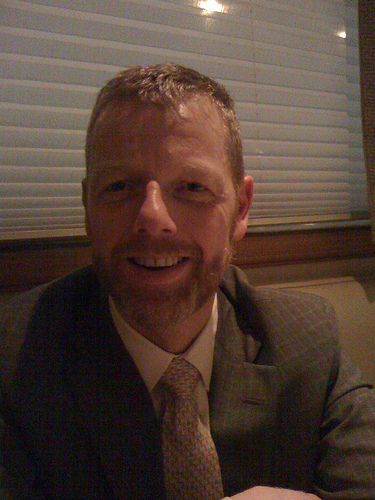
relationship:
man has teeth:
[1, 60, 374, 498] [128, 253, 185, 269]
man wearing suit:
[1, 60, 374, 498] [0, 261, 372, 500]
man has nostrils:
[1, 60, 374, 498] [133, 223, 173, 237]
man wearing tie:
[1, 60, 374, 498] [156, 356, 224, 500]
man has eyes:
[1, 60, 374, 498] [101, 175, 207, 192]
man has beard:
[1, 60, 374, 498] [86, 246, 228, 327]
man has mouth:
[1, 60, 374, 498] [124, 251, 194, 282]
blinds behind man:
[0, 0, 369, 238] [1, 60, 374, 498]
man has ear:
[1, 60, 374, 498] [231, 172, 256, 242]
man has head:
[1, 60, 374, 498] [77, 60, 255, 326]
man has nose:
[1, 60, 374, 498] [126, 177, 179, 237]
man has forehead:
[1, 60, 374, 498] [86, 94, 223, 163]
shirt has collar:
[106, 286, 221, 441] [104, 289, 219, 391]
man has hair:
[1, 60, 374, 498] [81, 59, 243, 187]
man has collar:
[1, 60, 374, 498] [104, 289, 219, 391]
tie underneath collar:
[156, 356, 224, 500] [104, 289, 219, 391]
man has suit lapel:
[1, 60, 374, 498] [242, 400, 303, 466]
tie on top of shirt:
[156, 356, 224, 500] [106, 286, 221, 441]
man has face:
[1, 60, 374, 498] [87, 93, 233, 324]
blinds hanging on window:
[0, 0, 369, 238] [1, 0, 373, 241]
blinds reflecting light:
[0, 0, 369, 238] [192, 0, 347, 42]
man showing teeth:
[1, 60, 374, 498] [128, 253, 185, 269]